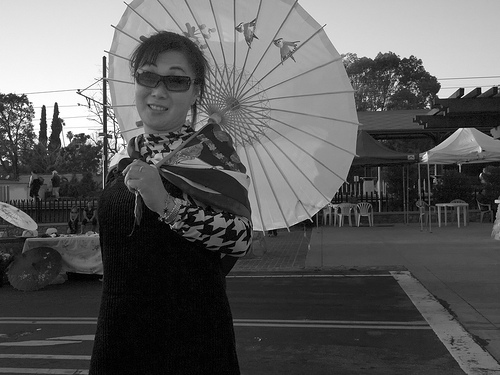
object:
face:
[29, 170, 35, 175]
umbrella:
[106, 0, 366, 237]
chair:
[353, 200, 376, 228]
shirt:
[132, 120, 255, 258]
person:
[79, 199, 100, 235]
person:
[26, 169, 44, 203]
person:
[48, 169, 63, 201]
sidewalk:
[217, 222, 500, 276]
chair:
[413, 199, 435, 224]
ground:
[1, 222, 500, 373]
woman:
[89, 29, 256, 374]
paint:
[387, 269, 500, 375]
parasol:
[100, 0, 366, 237]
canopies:
[413, 127, 500, 234]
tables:
[434, 202, 472, 228]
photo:
[0, 0, 500, 374]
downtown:
[0, 0, 500, 374]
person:
[65, 206, 84, 234]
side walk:
[308, 218, 500, 374]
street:
[1, 267, 500, 374]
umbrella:
[342, 128, 422, 226]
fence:
[0, 187, 438, 224]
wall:
[0, 224, 98, 238]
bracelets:
[160, 196, 185, 225]